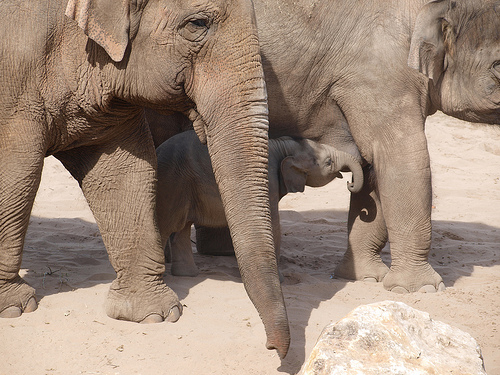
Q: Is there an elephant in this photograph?
A: Yes, there is an elephant.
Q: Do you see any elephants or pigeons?
A: Yes, there is an elephant.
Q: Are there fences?
A: No, there are no fences.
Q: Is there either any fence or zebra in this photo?
A: No, there are no fences or zebras.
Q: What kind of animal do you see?
A: The animal is an elephant.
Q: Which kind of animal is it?
A: The animal is an elephant.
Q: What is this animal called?
A: This is an elephant.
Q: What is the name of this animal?
A: This is an elephant.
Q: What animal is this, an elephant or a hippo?
A: This is an elephant.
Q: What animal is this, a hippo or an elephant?
A: This is an elephant.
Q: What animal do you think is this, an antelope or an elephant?
A: This is an elephant.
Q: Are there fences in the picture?
A: No, there are no fences.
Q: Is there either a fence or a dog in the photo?
A: No, there are no fences or dogs.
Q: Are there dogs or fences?
A: No, there are no fences or dogs.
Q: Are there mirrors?
A: No, there are no mirrors.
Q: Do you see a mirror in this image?
A: No, there are no mirrors.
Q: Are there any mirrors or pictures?
A: No, there are no mirrors or pictures.